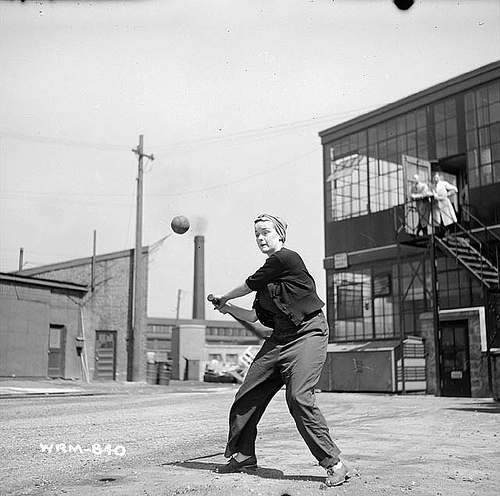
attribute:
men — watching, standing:
[409, 171, 459, 238]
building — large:
[318, 58, 499, 399]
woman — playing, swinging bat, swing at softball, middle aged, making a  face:
[207, 212, 352, 486]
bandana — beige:
[252, 210, 287, 243]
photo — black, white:
[1, 1, 499, 494]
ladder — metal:
[432, 233, 499, 291]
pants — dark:
[224, 310, 340, 468]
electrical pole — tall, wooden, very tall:
[129, 133, 155, 384]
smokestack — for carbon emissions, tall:
[192, 234, 207, 320]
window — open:
[326, 152, 361, 189]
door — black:
[400, 152, 436, 238]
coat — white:
[430, 181, 459, 227]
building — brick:
[16, 247, 154, 386]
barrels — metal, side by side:
[146, 357, 173, 387]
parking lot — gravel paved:
[0, 392, 499, 495]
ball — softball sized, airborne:
[171, 214, 191, 234]